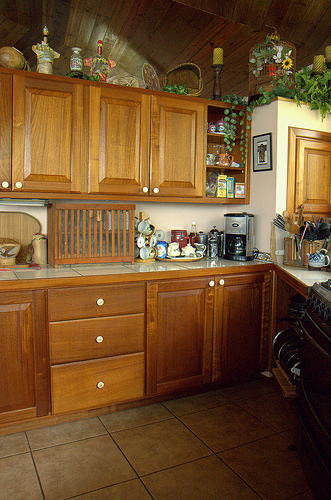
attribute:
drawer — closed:
[46, 280, 145, 320]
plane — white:
[218, 213, 260, 267]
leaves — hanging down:
[226, 106, 256, 155]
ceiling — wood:
[0, 0, 329, 95]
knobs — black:
[303, 285, 327, 320]